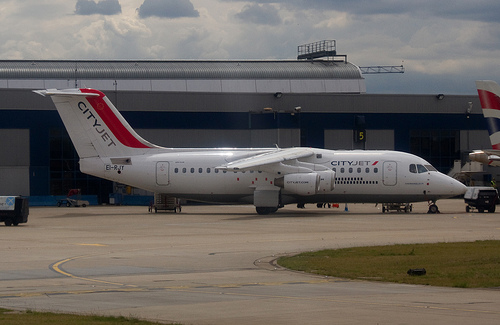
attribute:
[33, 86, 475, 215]
plane — striped, sitting, white, red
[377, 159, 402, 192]
door — white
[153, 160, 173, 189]
door — white